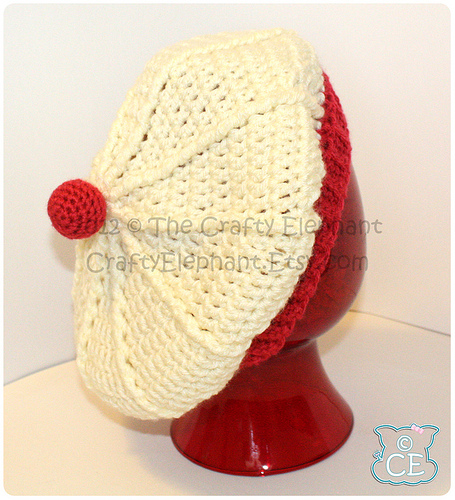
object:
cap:
[40, 26, 324, 422]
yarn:
[307, 74, 354, 249]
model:
[167, 169, 371, 480]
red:
[321, 118, 351, 158]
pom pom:
[44, 177, 110, 242]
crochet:
[264, 37, 309, 99]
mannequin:
[173, 159, 389, 464]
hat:
[45, 25, 353, 424]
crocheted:
[265, 31, 326, 177]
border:
[236, 52, 356, 371]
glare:
[245, 324, 329, 400]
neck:
[169, 341, 360, 474]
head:
[244, 176, 391, 360]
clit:
[140, 30, 294, 137]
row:
[217, 52, 259, 103]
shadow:
[123, 319, 448, 495]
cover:
[36, 24, 334, 399]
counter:
[6, 293, 449, 498]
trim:
[236, 56, 354, 370]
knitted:
[107, 40, 293, 161]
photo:
[0, 0, 450, 500]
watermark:
[363, 417, 445, 491]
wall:
[0, 0, 111, 143]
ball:
[45, 176, 109, 241]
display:
[44, 25, 367, 479]